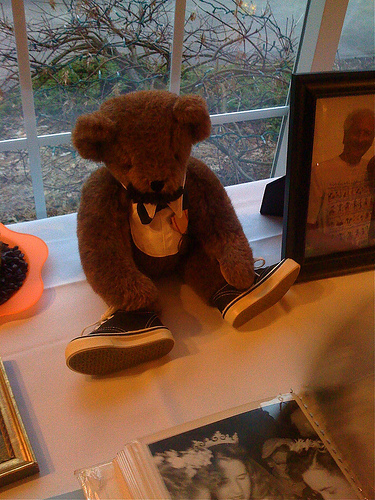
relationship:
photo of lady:
[157, 396, 369, 498] [149, 434, 291, 500]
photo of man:
[302, 93, 374, 258] [304, 107, 374, 258]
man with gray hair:
[304, 107, 374, 258] [344, 108, 374, 128]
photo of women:
[157, 396, 369, 498] [153, 426, 351, 500]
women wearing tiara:
[153, 426, 351, 500] [196, 432, 240, 445]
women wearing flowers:
[153, 426, 351, 500] [155, 448, 212, 476]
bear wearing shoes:
[65, 89, 300, 375] [212, 256, 301, 329]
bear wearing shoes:
[65, 89, 300, 375] [65, 305, 173, 375]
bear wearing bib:
[65, 89, 300, 375] [120, 174, 188, 258]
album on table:
[75, 388, 371, 500] [0, 174, 371, 498]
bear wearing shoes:
[65, 88, 300, 373] [71, 252, 303, 374]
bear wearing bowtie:
[65, 89, 300, 375] [126, 182, 185, 223]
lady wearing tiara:
[147, 438, 283, 497] [195, 432, 243, 475]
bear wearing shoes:
[65, 89, 300, 375] [48, 260, 315, 364]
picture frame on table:
[0, 359, 43, 492] [0, 174, 371, 498]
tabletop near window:
[287, 294, 372, 389] [7, 2, 289, 95]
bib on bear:
[114, 171, 188, 255] [65, 89, 300, 375]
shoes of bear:
[212, 254, 304, 329] [48, 62, 293, 369]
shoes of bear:
[65, 304, 173, 373] [48, 62, 293, 369]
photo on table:
[302, 93, 375, 258] [0, 174, 371, 498]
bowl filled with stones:
[0, 219, 50, 320] [0, 237, 28, 305]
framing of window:
[7, 48, 72, 157] [13, 13, 274, 83]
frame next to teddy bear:
[250, 66, 372, 292] [54, 86, 304, 377]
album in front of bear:
[75, 374, 372, 498] [65, 88, 300, 373]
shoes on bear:
[71, 252, 303, 374] [65, 88, 300, 373]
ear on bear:
[71, 113, 114, 162] [65, 88, 300, 373]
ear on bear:
[174, 93, 210, 141] [65, 88, 300, 373]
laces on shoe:
[80, 305, 118, 333] [64, 307, 173, 375]